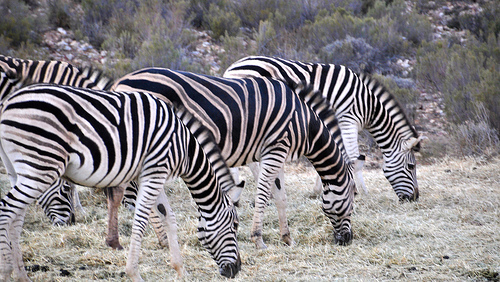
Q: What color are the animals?
A: Black and white.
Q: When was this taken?
A: During the day.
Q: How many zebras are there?
A: 4.